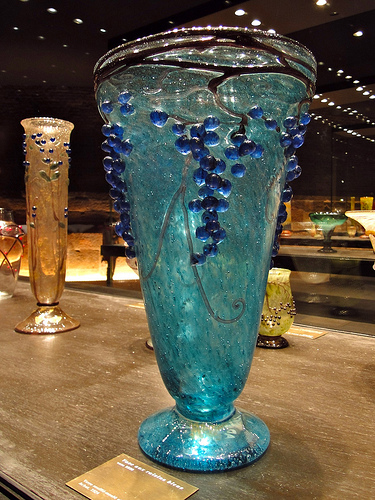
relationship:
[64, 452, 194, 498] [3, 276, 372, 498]
place card at table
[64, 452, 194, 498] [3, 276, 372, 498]
place card on top of table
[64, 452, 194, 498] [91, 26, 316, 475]
place card in front of vase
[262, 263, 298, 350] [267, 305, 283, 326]
glass with beads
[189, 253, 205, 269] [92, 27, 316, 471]
dot on cup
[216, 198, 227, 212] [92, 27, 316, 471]
dot on cup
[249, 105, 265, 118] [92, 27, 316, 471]
dot on cup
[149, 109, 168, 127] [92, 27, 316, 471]
dot on cup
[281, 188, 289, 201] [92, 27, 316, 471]
dot on cup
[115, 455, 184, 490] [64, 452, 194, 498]
lettering on place card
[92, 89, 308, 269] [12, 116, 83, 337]
blue stones on vase